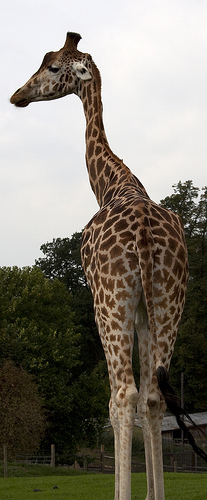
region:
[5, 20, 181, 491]
the giraffe on the grass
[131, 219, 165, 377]
the tail of the giraffe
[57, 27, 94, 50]
ossicones on the head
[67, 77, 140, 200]
the neck of the giraffe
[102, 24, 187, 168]
the sky is blue and clear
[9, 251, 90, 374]
trees with green leaves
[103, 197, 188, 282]
the rump of the giraffe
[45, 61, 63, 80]
the eye of the giraffe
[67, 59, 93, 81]
the ear of the giraffe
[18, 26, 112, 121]
head of the giraffe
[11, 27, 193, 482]
brown giraffe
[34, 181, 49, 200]
white clouds in blue sky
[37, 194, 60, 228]
white clouds in blue sky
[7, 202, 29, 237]
white clouds in blue sky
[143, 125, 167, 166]
white clouds in blue sky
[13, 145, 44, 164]
white clouds in blue sky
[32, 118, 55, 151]
white clouds in blue sky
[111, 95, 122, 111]
white clouds in blue sky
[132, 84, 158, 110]
white clouds in blue sky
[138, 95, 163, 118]
white clouds in blue sky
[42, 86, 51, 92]
brown spot on giraffe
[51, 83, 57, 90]
brown spot on giraffe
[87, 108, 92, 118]
brown spot on giraffe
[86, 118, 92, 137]
brown spot on giraffe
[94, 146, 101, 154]
brown spot on giraffe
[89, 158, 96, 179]
brown spot on giraffe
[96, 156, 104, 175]
brown spot on giraffe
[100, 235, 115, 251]
brown spot on giraffe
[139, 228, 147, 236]
brown spot on giraffe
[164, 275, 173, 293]
brown spot on giraffe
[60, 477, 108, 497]
patch of green grass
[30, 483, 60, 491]
possibly giraffe poop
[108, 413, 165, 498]
four legs of giraffe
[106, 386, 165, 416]
four giraffe knees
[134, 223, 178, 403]
tail of giraffe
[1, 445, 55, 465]
wooden poles forming fence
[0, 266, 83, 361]
large, tall tree with green leaves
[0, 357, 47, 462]
smaller tree closer to ground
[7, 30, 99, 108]
giraffe head looking sideways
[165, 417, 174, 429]
roof of building